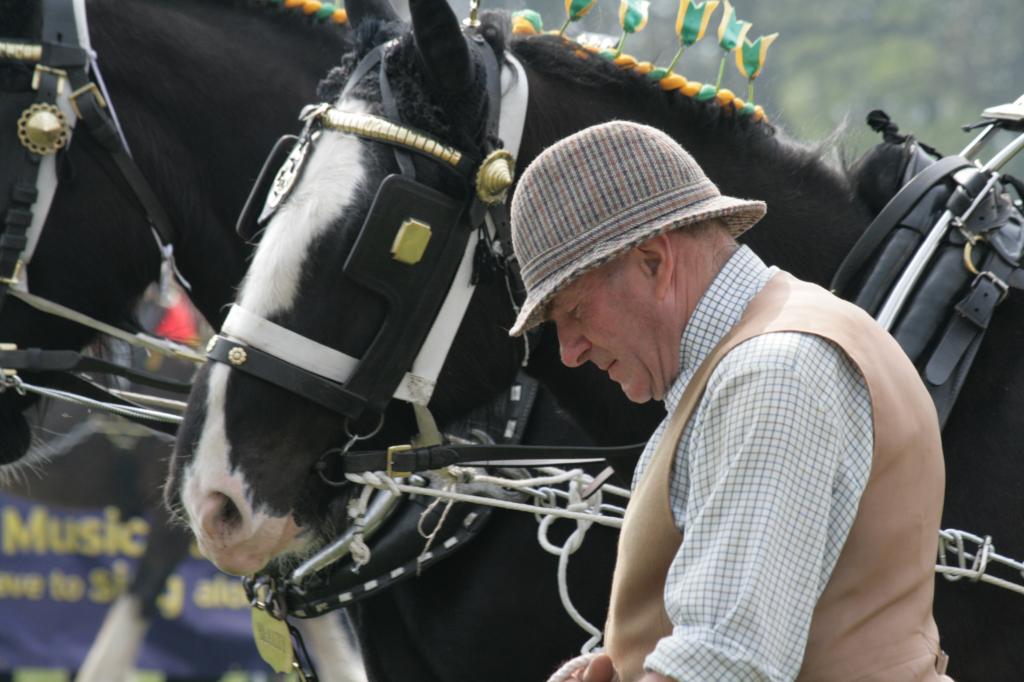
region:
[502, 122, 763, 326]
checkered hat on man's head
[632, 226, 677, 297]
left ear on man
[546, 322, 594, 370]
nose on the man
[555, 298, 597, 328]
left eye on man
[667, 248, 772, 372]
collar on the man's shirt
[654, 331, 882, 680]
sleeve on the man's shirt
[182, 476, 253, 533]
left nostril on horse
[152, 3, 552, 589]
head on the horse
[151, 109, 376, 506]
white stripe on the horse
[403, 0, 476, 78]
left ear on horse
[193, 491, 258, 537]
nostril of the horse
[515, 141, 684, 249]
man is wearing a hat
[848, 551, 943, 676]
a vest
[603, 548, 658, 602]
vest is brown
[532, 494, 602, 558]
a white string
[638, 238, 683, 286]
ear of the man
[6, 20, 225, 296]
a horse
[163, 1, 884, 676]
black and white horse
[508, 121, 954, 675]
old man in a hat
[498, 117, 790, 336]
brown and white wool bucket hat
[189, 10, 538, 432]
black leather horse bridal with decorations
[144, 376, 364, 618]
pink white and black horse nose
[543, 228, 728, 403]
face of an elderly white man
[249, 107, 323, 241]
small gold ornament for the bridle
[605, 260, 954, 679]
light brown vest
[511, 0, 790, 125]
yellow and green mane decorations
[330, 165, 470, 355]
black and gold blinders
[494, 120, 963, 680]
an older man walks aside the horses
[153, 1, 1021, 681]
the horse is black with a white spot on its muzzle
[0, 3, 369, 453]
there is another black horse next to the first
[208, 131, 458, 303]
the horse is wearing blinders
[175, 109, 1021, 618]
the horse is wearing a harness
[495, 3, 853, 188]
the horse's main is decorated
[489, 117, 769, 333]
the man wears a tweed hat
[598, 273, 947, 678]
the man wears a tan vest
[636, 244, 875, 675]
the man is wearing a checked shirt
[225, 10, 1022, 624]
the horses harness is made of black leather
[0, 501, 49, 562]
yellow letter on sign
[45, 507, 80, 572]
yellow letter on sign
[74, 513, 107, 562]
yellow letter on sign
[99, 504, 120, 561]
yellow letter on sign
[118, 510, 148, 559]
yellow letter on sign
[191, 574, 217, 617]
yellow letter on sign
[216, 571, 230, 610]
yellow letter on sign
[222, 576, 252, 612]
yellow letter on sign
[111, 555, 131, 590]
yellow letter on sign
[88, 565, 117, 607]
yellow letter on sign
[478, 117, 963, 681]
the man wears a bucket hat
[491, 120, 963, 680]
the man is looking down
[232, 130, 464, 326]
the horse next to the man has black leather blinders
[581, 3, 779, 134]
horse has a green and orange ribbon in its mane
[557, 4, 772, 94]
There are green and orange flags sticking out of the ribbon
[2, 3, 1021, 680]
both horses are large and black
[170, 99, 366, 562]
one horse has a white mark on the front of his face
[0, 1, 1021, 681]
the horses are draft horses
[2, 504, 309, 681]
there is a purple banner behind the horses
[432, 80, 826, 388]
head of the man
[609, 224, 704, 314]
ear of the man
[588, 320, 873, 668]
arm of the man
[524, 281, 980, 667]
brown and white outfit